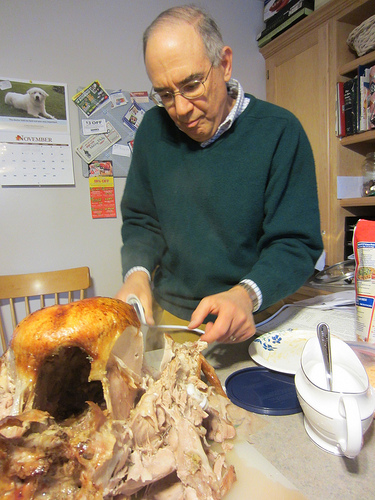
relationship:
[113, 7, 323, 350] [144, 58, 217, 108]
man wearing glasses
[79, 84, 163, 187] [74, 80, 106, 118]
board has post card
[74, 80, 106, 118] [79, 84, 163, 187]
post card on board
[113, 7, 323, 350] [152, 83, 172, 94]
man has eyebrow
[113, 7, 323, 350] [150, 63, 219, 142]
man has face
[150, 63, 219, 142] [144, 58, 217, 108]
face has glasses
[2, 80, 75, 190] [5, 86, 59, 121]
poster has dog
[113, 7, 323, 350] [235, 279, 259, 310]
man has watch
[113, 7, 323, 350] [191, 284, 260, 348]
man has hand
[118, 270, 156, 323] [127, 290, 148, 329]
hand has carving knife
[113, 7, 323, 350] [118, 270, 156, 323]
man has hand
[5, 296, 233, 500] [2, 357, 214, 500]
turkey on platter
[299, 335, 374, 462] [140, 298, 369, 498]
gravy bowl on table top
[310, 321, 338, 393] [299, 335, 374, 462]
utensil in gravy bowl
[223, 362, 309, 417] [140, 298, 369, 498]
lid on table top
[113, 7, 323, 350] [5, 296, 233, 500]
man looking at turkey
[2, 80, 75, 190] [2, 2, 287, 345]
poster hanging on wall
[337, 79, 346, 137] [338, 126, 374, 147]
book sitting on shelf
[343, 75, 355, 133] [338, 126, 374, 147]
book sitting on shelf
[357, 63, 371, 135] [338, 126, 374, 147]
book sitting on shelf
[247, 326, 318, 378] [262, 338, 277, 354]
saucer has flower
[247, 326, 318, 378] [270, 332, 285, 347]
saucer has flower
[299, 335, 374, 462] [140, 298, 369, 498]
gravy bowl on top of table top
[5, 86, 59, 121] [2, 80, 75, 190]
dog printed on poster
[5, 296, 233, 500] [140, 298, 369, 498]
turkey sitting on table top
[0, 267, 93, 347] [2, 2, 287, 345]
chair against wall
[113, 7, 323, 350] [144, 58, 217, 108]
man has glasses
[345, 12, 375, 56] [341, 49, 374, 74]
basket sitting on top shelf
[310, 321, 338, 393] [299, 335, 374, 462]
utensil inside gravy bowl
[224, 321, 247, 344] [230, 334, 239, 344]
finger has ring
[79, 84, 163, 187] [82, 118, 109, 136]
board has coupon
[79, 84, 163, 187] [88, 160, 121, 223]
board has coupon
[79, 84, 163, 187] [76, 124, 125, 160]
board has coupon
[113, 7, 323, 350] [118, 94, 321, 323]
man wearing sweater